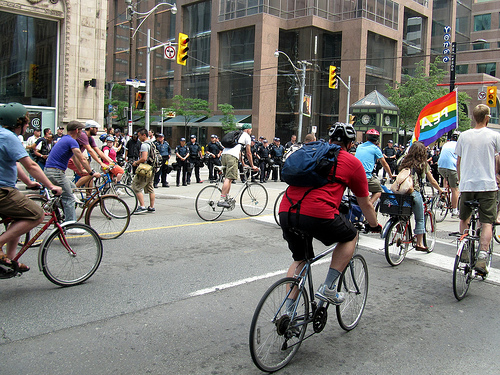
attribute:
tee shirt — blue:
[45, 135, 81, 172]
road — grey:
[45, 89, 457, 374]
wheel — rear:
[248, 273, 314, 373]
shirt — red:
[313, 188, 338, 210]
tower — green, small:
[349, 88, 401, 133]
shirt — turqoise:
[354, 140, 384, 179]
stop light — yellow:
[321, 65, 338, 89]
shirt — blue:
[50, 144, 71, 163]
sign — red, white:
[162, 45, 178, 60]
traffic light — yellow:
[175, 31, 191, 66]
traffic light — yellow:
[328, 65, 336, 90]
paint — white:
[186, 253, 338, 300]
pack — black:
[220, 126, 235, 142]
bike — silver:
[244, 192, 389, 374]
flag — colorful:
[395, 90, 457, 165]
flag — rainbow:
[407, 83, 463, 143]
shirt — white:
[454, 129, 484, 194]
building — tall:
[9, 57, 133, 207]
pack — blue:
[255, 113, 357, 206]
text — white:
[423, 100, 463, 130]